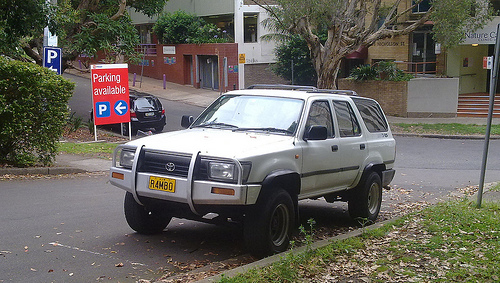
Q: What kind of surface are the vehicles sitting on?
A: Paved.